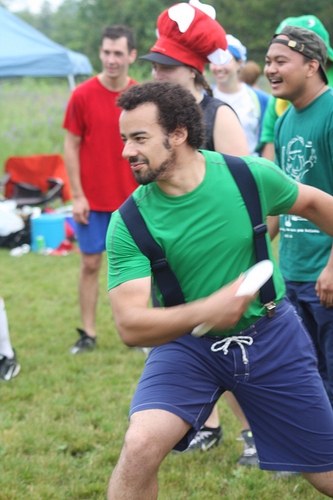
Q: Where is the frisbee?
A: In the man in green's hand.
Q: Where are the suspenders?
A: On the player in green.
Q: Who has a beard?
A: The man in front.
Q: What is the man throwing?
A: Frisbee.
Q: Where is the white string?
A: Shorts.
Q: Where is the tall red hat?
A: Woman's head behind the man in suspenders.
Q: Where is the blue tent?
A: Behind the people.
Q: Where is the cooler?
A: Under the tent.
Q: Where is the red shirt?
A: Man behind the woman in the red hat.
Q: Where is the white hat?
A: Behind the red hat.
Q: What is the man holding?
A: A Frisbee.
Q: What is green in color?
A: The shirt.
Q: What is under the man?
A: The grass.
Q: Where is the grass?
A: On the ground.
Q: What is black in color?
A: The suspenders.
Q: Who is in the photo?
A: Some people.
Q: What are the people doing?
A: Standing.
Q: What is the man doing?
A: Throwing a Frisbee.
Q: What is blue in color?
A: The shorts.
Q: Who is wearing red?
A: Man in the background.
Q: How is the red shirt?
A: Short sleeved.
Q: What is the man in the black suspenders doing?
A: Throwing a frisbee.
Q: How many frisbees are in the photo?
A: One.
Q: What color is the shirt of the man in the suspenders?
A: Green.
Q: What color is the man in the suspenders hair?
A: Dark brown.